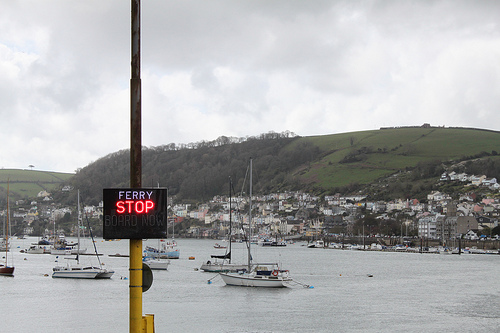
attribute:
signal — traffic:
[86, 172, 179, 242]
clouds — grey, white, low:
[1, 1, 499, 174]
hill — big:
[0, 127, 499, 211]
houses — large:
[441, 170, 499, 190]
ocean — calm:
[1, 235, 499, 333]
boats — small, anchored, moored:
[0, 234, 499, 289]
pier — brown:
[308, 245, 500, 258]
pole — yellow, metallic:
[129, 0, 143, 333]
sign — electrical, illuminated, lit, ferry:
[102, 187, 167, 239]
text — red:
[115, 190, 155, 213]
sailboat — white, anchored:
[218, 158, 291, 288]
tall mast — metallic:
[246, 157, 252, 272]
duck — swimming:
[366, 274, 372, 277]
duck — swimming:
[311, 273, 315, 275]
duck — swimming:
[43, 274, 49, 277]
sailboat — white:
[52, 189, 114, 279]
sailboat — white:
[143, 183, 169, 269]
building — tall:
[444, 201, 478, 240]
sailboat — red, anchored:
[1, 174, 16, 277]